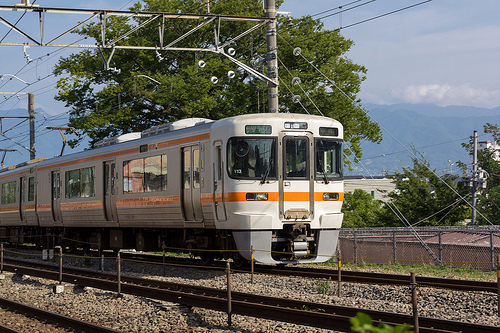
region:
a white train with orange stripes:
[0, 107, 346, 270]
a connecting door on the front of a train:
[276, 128, 317, 226]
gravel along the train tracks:
[202, 271, 403, 317]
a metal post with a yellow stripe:
[333, 248, 344, 298]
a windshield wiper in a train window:
[315, 145, 330, 188]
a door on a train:
[177, 139, 205, 226]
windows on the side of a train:
[122, 151, 170, 194]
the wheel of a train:
[192, 229, 217, 265]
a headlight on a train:
[243, 189, 270, 202]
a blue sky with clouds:
[0, 2, 498, 185]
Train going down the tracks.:
[2, 103, 392, 273]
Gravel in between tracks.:
[162, 265, 229, 287]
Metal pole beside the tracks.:
[214, 255, 238, 327]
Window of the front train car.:
[231, 135, 281, 180]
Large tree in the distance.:
[59, 3, 400, 145]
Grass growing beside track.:
[360, 254, 487, 278]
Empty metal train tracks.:
[88, 259, 310, 331]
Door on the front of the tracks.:
[271, 123, 324, 233]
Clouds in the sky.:
[390, 75, 498, 113]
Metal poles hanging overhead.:
[18, 5, 284, 71]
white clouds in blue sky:
[371, 11, 419, 55]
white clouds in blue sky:
[418, 15, 476, 69]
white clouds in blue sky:
[381, 46, 453, 113]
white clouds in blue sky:
[401, 86, 443, 131]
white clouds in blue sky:
[2, 26, 49, 77]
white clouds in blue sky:
[11, 75, 75, 126]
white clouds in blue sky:
[361, 32, 432, 74]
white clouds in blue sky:
[462, 56, 493, 91]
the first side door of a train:
[175, 136, 216, 220]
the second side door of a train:
[98, 152, 130, 230]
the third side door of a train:
[38, 163, 66, 227]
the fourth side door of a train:
[8, 176, 30, 216]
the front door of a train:
[271, 125, 322, 222]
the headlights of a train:
[232, 188, 344, 213]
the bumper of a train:
[237, 221, 342, 268]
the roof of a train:
[81, 112, 255, 153]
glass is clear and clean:
[228, 136, 280, 177]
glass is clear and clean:
[282, 138, 307, 175]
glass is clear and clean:
[316, 136, 339, 174]